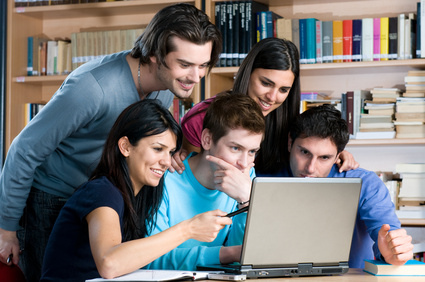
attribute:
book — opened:
[85, 266, 213, 279]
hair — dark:
[88, 96, 183, 235]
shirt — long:
[0, 49, 175, 230]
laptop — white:
[196, 175, 361, 277]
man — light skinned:
[1, 4, 221, 279]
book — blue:
[361, 255, 424, 275]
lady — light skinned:
[52, 98, 232, 280]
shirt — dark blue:
[47, 175, 147, 279]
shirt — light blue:
[141, 149, 256, 268]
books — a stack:
[355, 80, 412, 138]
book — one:
[384, 8, 402, 58]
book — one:
[338, 91, 362, 142]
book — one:
[326, 17, 344, 62]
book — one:
[342, 20, 351, 59]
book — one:
[349, 20, 360, 63]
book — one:
[359, 10, 379, 66]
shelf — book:
[203, 6, 423, 267]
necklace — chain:
[131, 56, 150, 97]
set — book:
[214, 7, 263, 61]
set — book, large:
[57, 26, 152, 63]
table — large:
[101, 258, 423, 277]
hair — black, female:
[263, 43, 288, 65]